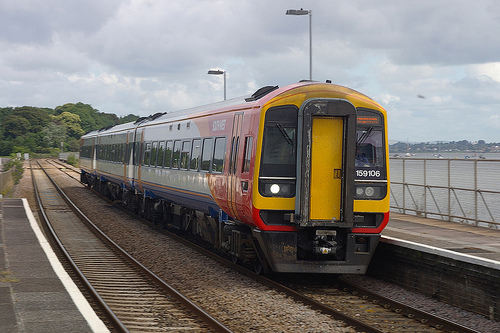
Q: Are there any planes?
A: No, there are no planes.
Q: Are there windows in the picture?
A: Yes, there is a window.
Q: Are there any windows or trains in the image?
A: Yes, there is a window.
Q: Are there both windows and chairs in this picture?
A: No, there is a window but no chairs.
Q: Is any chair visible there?
A: No, there are no chairs.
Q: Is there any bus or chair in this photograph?
A: No, there are no chairs or buses.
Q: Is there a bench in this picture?
A: No, there are no benches.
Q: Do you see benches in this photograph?
A: No, there are no benches.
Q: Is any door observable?
A: Yes, there is a door.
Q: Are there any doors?
A: Yes, there is a door.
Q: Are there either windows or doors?
A: Yes, there is a door.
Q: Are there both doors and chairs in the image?
A: No, there is a door but no chairs.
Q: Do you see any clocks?
A: No, there are no clocks.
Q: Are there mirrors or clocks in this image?
A: No, there are no clocks or mirrors.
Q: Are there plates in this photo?
A: Yes, there is a plate.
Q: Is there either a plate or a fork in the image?
A: Yes, there is a plate.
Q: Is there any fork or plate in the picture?
A: Yes, there is a plate.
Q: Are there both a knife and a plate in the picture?
A: No, there is a plate but no knives.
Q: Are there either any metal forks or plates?
A: Yes, there is a metal plate.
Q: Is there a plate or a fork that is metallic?
A: Yes, the plate is metallic.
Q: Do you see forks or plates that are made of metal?
A: Yes, the plate is made of metal.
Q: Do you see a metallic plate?
A: Yes, there is a metal plate.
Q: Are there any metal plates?
A: Yes, there is a metal plate.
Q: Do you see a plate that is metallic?
A: Yes, there is a plate that is metallic.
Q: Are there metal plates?
A: Yes, there is a plate that is made of metal.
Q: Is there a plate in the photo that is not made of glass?
A: Yes, there is a plate that is made of metal.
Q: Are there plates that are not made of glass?
A: Yes, there is a plate that is made of metal.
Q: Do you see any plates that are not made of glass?
A: Yes, there is a plate that is made of metal.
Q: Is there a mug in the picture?
A: No, there are no mugs.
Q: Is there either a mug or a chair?
A: No, there are no mugs or chairs.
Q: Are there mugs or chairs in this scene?
A: No, there are no mugs or chairs.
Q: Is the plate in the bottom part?
A: Yes, the plate is in the bottom of the image.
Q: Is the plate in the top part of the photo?
A: No, the plate is in the bottom of the image.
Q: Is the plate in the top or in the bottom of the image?
A: The plate is in the bottom of the image.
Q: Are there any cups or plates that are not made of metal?
A: No, there is a plate but it is made of metal.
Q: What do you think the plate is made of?
A: The plate is made of metal.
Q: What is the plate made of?
A: The plate is made of metal.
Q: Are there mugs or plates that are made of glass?
A: No, there is a plate but it is made of metal.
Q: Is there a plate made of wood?
A: No, there is a plate but it is made of metal.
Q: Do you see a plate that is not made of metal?
A: No, there is a plate but it is made of metal.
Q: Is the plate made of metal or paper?
A: The plate is made of metal.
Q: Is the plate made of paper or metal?
A: The plate is made of metal.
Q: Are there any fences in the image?
A: Yes, there is a fence.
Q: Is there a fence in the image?
A: Yes, there is a fence.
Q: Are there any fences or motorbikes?
A: Yes, there is a fence.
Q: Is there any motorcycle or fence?
A: Yes, there is a fence.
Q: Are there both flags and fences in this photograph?
A: No, there is a fence but no flags.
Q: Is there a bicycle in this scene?
A: No, there are no bicycles.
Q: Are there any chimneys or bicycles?
A: No, there are no bicycles or chimneys.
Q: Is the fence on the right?
A: Yes, the fence is on the right of the image.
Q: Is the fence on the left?
A: No, the fence is on the right of the image.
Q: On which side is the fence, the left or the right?
A: The fence is on the right of the image.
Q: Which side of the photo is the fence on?
A: The fence is on the right of the image.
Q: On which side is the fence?
A: The fence is on the right of the image.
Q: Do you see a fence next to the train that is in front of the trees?
A: Yes, there is a fence next to the train.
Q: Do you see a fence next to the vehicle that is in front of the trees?
A: Yes, there is a fence next to the train.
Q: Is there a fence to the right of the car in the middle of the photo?
A: Yes, there is a fence to the right of the car.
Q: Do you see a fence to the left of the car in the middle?
A: No, the fence is to the right of the car.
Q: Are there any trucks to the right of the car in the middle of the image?
A: No, there is a fence to the right of the car.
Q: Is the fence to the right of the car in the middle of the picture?
A: Yes, the fence is to the right of the car.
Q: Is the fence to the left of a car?
A: No, the fence is to the right of a car.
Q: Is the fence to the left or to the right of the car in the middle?
A: The fence is to the right of the car.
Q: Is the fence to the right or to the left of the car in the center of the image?
A: The fence is to the right of the car.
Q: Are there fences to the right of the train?
A: Yes, there is a fence to the right of the train.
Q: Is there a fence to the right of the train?
A: Yes, there is a fence to the right of the train.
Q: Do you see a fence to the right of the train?
A: Yes, there is a fence to the right of the train.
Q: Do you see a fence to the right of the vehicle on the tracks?
A: Yes, there is a fence to the right of the train.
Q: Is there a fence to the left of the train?
A: No, the fence is to the right of the train.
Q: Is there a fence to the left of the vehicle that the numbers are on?
A: No, the fence is to the right of the train.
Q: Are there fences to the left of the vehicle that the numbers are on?
A: No, the fence is to the right of the train.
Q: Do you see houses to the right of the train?
A: No, there is a fence to the right of the train.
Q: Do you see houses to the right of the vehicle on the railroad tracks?
A: No, there is a fence to the right of the train.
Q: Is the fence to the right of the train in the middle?
A: Yes, the fence is to the right of the train.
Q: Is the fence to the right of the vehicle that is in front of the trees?
A: Yes, the fence is to the right of the train.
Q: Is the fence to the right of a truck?
A: No, the fence is to the right of the train.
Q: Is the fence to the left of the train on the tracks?
A: No, the fence is to the right of the train.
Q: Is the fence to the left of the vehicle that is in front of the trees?
A: No, the fence is to the right of the train.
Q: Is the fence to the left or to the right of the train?
A: The fence is to the right of the train.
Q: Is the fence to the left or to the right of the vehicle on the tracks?
A: The fence is to the right of the train.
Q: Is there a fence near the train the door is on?
A: Yes, there is a fence near the train.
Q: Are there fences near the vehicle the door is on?
A: Yes, there is a fence near the train.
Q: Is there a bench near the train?
A: No, there is a fence near the train.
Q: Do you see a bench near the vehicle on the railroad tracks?
A: No, there is a fence near the train.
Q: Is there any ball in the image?
A: No, there are no balls.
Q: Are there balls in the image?
A: No, there are no balls.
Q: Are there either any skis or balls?
A: No, there are no balls or skis.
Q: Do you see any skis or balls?
A: No, there are no balls or skis.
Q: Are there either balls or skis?
A: No, there are no balls or skis.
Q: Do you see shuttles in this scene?
A: No, there are no shuttles.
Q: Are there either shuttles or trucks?
A: No, there are no shuttles or trucks.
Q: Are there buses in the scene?
A: No, there are no buses.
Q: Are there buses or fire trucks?
A: No, there are no buses or fire trucks.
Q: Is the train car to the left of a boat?
A: Yes, the car is to the left of a boat.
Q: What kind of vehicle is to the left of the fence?
A: The vehicle is a car.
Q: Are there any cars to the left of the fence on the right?
A: Yes, there is a car to the left of the fence.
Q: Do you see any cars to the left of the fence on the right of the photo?
A: Yes, there is a car to the left of the fence.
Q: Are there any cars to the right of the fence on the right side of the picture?
A: No, the car is to the left of the fence.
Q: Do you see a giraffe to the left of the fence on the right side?
A: No, there is a car to the left of the fence.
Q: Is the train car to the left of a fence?
A: Yes, the car is to the left of a fence.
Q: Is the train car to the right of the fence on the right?
A: No, the car is to the left of the fence.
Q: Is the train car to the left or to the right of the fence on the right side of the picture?
A: The car is to the left of the fence.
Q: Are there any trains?
A: Yes, there is a train.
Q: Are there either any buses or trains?
A: Yes, there is a train.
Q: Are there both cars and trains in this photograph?
A: Yes, there are both a train and a car.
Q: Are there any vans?
A: No, there are no vans.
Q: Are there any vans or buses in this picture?
A: No, there are no vans or buses.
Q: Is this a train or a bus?
A: This is a train.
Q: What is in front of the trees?
A: The train is in front of the trees.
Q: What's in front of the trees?
A: The train is in front of the trees.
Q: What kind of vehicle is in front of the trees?
A: The vehicle is a train.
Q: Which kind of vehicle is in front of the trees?
A: The vehicle is a train.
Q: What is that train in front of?
A: The train is in front of the trees.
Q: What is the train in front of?
A: The train is in front of the trees.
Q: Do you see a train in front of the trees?
A: Yes, there is a train in front of the trees.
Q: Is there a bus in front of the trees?
A: No, there is a train in front of the trees.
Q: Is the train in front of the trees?
A: Yes, the train is in front of the trees.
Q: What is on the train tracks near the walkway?
A: The train is on the train tracks.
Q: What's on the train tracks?
A: The train is on the train tracks.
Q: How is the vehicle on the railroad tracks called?
A: The vehicle is a train.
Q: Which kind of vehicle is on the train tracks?
A: The vehicle is a train.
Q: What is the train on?
A: The train is on the train tracks.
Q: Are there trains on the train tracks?
A: Yes, there is a train on the train tracks.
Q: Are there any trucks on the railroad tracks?
A: No, there is a train on the railroad tracks.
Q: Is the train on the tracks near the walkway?
A: Yes, the train is on the train tracks.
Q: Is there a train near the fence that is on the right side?
A: Yes, there is a train near the fence.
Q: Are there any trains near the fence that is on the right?
A: Yes, there is a train near the fence.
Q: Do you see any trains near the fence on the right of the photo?
A: Yes, there is a train near the fence.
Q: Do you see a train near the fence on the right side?
A: Yes, there is a train near the fence.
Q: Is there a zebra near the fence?
A: No, there is a train near the fence.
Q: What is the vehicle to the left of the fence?
A: The vehicle is a train.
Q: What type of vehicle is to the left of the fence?
A: The vehicle is a train.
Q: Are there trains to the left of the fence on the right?
A: Yes, there is a train to the left of the fence.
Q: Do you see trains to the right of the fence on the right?
A: No, the train is to the left of the fence.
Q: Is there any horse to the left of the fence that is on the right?
A: No, there is a train to the left of the fence.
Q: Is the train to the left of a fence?
A: Yes, the train is to the left of a fence.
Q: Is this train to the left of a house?
A: No, the train is to the left of a fence.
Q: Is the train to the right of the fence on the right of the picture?
A: No, the train is to the left of the fence.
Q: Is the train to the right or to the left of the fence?
A: The train is to the left of the fence.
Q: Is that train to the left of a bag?
A: No, the train is to the left of a boat.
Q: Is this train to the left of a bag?
A: No, the train is to the left of a boat.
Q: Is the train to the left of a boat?
A: Yes, the train is to the left of a boat.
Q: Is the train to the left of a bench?
A: No, the train is to the left of a boat.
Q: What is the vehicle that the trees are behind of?
A: The vehicle is a train.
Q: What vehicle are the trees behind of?
A: The trees are behind the train.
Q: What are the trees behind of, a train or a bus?
A: The trees are behind a train.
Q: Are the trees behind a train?
A: Yes, the trees are behind a train.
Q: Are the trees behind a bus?
A: No, the trees are behind a train.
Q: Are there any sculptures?
A: No, there are no sculptures.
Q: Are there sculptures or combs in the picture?
A: No, there are no sculptures or combs.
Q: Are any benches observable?
A: No, there are no benches.